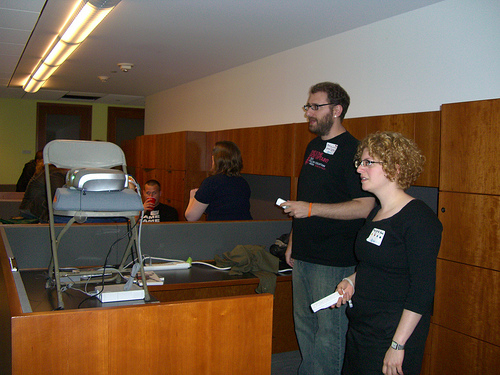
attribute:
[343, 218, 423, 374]
clothing — black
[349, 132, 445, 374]
woman — standing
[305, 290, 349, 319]
controller — white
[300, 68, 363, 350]
man — standing, drinking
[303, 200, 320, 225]
wristband — orange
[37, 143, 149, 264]
chair — folding, gray, grey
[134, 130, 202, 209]
cabinets — wooden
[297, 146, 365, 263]
shirt — black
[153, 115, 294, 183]
wall — brown, wooden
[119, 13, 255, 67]
ceiling — white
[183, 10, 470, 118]
wall — white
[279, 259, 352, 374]
jeans — blue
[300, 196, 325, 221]
bracelet — orange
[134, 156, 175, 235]
man — drinking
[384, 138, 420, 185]
hair — brown, curly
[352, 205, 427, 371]
dress — black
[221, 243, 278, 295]
garment — green